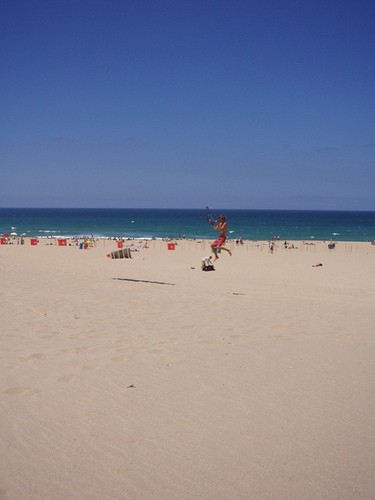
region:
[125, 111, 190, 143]
Nice summer blue sky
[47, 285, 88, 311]
Beige sandy summer beach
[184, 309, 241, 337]
Beige summer sandy beach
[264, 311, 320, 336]
Beige summer sandy beach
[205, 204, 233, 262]
Happy person playing frisbee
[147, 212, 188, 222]
Nice blue ocean water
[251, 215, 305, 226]
Nice blue ocean water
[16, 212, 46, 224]
Nice blue ocean water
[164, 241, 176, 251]
Summer ocean beach chair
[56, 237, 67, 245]
Summer ocean beach chair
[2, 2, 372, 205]
blue of daytime sky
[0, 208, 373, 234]
surface of ocean water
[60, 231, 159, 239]
whtie caps of waves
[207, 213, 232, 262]
man holding rod of parasail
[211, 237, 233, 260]
legs in red shorts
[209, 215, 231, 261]
shirtless man in the air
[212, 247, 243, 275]
legs above sand surface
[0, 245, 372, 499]
sand on surface of beach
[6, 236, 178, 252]
red barrels in sand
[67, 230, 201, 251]
people on beach sand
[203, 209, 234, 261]
jumping man on beach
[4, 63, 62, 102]
white clouds in blue sky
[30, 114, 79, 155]
white clouds in blue sky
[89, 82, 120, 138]
white clouds in blue sky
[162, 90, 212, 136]
white clouds in blue sky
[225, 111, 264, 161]
white clouds in blue sky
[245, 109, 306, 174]
white clouds in blue sky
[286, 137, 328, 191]
white clouds in blue sky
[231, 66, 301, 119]
white clouds in blue sky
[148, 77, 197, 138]
white clouds in blue sky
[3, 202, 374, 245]
Blue ocean with waves coming into shore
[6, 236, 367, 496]
Light colored sandy beach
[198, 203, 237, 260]
Boy floating in air holding onto handle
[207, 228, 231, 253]
Red board shorts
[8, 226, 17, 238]
White umbrella on beach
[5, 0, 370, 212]
Bright blue sky with no clouds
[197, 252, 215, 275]
Man in white shirt rolling something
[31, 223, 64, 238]
White crest of wave rolling to shore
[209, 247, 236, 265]
Two bare feet of young guy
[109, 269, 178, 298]
Shadow of object above beach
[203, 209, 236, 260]
man jumping in air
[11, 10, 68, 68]
white clouds in blue sky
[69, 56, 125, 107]
white clouds in blue sky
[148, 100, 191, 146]
white clouds in blue sky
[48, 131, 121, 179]
white clouds in blue sky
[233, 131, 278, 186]
white clouds in blue sky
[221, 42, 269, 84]
white clouds in blue sky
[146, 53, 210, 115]
white clouds in blue sky